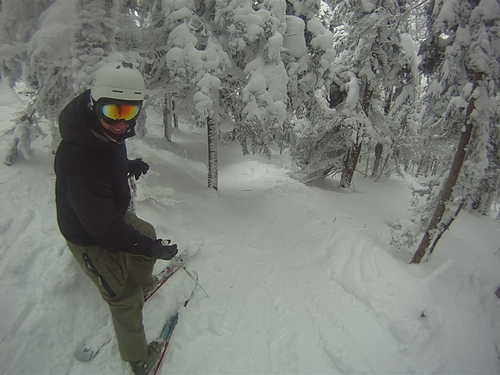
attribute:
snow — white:
[210, 197, 382, 371]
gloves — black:
[150, 238, 171, 257]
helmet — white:
[86, 59, 146, 110]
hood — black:
[56, 58, 128, 148]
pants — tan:
[45, 212, 211, 371]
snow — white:
[218, 172, 320, 269]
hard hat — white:
[88, 60, 145, 104]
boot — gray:
[107, 331, 174, 373]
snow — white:
[111, 162, 229, 312]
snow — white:
[140, 139, 253, 362]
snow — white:
[151, 16, 310, 101]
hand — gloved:
[147, 238, 180, 258]